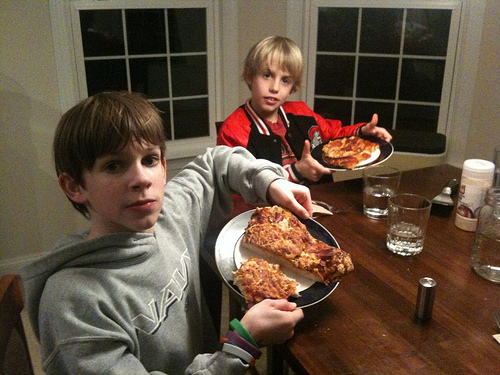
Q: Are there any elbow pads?
A: No, there are no elbow pads.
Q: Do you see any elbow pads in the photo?
A: No, there are no elbow pads.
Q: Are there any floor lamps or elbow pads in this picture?
A: No, there are no elbow pads or floor lamps.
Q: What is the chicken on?
A: The chicken is on the plate.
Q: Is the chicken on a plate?
A: Yes, the chicken is on a plate.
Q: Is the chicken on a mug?
A: No, the chicken is on a plate.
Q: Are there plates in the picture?
A: Yes, there is a plate.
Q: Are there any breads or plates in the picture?
A: Yes, there is a plate.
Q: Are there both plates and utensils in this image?
A: No, there is a plate but no utensils.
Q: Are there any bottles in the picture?
A: No, there are no bottles.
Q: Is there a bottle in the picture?
A: No, there are no bottles.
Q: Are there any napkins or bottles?
A: No, there are no bottles or napkins.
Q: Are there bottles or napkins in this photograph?
A: No, there are no bottles or napkins.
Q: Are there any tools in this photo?
A: No, there are no tools.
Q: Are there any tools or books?
A: No, there are no tools or books.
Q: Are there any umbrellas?
A: No, there are no umbrellas.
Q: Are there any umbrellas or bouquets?
A: No, there are no umbrellas or bouquets.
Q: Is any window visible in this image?
A: Yes, there is a window.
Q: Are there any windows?
A: Yes, there is a window.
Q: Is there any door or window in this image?
A: Yes, there is a window.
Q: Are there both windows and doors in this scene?
A: No, there is a window but no doors.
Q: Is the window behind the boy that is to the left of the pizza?
A: Yes, the window is behind the boy.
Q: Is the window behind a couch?
A: No, the window is behind the boy.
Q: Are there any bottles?
A: No, there are no bottles.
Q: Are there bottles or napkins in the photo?
A: No, there are no bottles or napkins.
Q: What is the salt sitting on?
A: The salt is sitting on the table.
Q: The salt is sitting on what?
A: The salt is sitting on the table.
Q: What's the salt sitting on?
A: The salt is sitting on the table.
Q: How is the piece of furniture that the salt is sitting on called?
A: The piece of furniture is a table.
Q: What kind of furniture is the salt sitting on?
A: The salt is sitting on the table.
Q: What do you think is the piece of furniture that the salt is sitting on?
A: The piece of furniture is a table.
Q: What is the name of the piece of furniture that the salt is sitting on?
A: The piece of furniture is a table.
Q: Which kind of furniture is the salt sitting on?
A: The salt is sitting on the table.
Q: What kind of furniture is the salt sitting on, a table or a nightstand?
A: The salt is sitting on a table.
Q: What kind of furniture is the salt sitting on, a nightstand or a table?
A: The salt is sitting on a table.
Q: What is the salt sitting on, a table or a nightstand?
A: The salt is sitting on a table.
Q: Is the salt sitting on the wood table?
A: Yes, the salt is sitting on the table.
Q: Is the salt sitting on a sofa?
A: No, the salt is sitting on the table.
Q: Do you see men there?
A: No, there are no men.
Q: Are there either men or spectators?
A: No, there are no men or spectators.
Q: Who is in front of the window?
A: The boy is in front of the window.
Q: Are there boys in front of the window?
A: Yes, there is a boy in front of the window.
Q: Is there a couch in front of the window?
A: No, there is a boy in front of the window.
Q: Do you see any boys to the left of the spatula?
A: Yes, there is a boy to the left of the spatula.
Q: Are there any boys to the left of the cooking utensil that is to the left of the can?
A: Yes, there is a boy to the left of the spatula.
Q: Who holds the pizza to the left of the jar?
A: The boy holds the pizza.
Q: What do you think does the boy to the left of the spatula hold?
A: The boy holds the pizza.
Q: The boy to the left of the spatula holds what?
A: The boy holds the pizza.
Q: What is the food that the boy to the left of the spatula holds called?
A: The food is a pizza.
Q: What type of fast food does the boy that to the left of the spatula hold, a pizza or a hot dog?
A: The boy holds a pizza.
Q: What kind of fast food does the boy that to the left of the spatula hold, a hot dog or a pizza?
A: The boy holds a pizza.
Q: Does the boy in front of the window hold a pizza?
A: Yes, the boy holds a pizza.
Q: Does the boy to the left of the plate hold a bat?
A: No, the boy holds a pizza.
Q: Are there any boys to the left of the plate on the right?
A: Yes, there is a boy to the left of the plate.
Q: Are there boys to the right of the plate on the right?
A: No, the boy is to the left of the plate.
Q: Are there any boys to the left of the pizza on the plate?
A: Yes, there is a boy to the left of the pizza.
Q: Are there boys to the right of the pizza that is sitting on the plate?
A: No, the boy is to the left of the pizza.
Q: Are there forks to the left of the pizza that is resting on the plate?
A: No, there is a boy to the left of the pizza.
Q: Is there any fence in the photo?
A: No, there are no fences.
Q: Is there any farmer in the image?
A: No, there are no farmers.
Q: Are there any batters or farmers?
A: No, there are no farmers or batters.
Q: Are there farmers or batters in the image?
A: No, there are no farmers or batters.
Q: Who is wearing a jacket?
A: The boy is wearing a jacket.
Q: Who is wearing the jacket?
A: The boy is wearing a jacket.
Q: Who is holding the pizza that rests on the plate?
A: The boy is holding the pizza.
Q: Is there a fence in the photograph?
A: No, there are no fences.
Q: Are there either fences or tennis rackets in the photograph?
A: No, there are no fences or tennis rackets.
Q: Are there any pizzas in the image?
A: Yes, there is a pizza.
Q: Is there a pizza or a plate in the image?
A: Yes, there is a pizza.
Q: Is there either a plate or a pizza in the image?
A: Yes, there is a pizza.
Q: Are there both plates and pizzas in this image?
A: Yes, there are both a pizza and a plate.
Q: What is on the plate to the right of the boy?
A: The pizza is on the plate.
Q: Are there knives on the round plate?
A: No, there is a pizza on the plate.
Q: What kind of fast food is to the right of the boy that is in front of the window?
A: The food is a pizza.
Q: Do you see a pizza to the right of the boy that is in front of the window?
A: Yes, there is a pizza to the right of the boy.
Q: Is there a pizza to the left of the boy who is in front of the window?
A: No, the pizza is to the right of the boy.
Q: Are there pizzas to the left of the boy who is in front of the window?
A: No, the pizza is to the right of the boy.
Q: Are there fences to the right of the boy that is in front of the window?
A: No, there is a pizza to the right of the boy.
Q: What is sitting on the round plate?
A: The pizza is sitting on the plate.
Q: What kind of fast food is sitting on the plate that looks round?
A: The food is a pizza.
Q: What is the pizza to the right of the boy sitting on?
A: The pizza is sitting on the plate.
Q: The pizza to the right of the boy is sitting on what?
A: The pizza is sitting on the plate.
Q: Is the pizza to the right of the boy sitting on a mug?
A: No, the pizza is sitting on the plate.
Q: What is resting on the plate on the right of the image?
A: The pizza is resting on the plate.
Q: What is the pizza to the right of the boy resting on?
A: The pizza is resting on the plate.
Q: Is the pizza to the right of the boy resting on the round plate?
A: Yes, the pizza is resting on the plate.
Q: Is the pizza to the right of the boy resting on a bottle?
A: No, the pizza is resting on the plate.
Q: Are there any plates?
A: Yes, there is a plate.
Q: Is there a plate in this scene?
A: Yes, there is a plate.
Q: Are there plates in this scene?
A: Yes, there is a plate.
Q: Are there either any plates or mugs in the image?
A: Yes, there is a plate.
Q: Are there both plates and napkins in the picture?
A: No, there is a plate but no napkins.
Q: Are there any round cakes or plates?
A: Yes, there is a round plate.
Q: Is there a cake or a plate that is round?
A: Yes, the plate is round.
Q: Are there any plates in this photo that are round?
A: Yes, there is a round plate.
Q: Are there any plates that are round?
A: Yes, there is a plate that is round.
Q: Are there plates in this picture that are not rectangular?
A: Yes, there is a round plate.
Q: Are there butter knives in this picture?
A: No, there are no butter knives.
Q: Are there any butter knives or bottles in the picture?
A: No, there are no butter knives or bottles.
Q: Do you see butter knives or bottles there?
A: No, there are no butter knives or bottles.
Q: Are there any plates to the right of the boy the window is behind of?
A: Yes, there is a plate to the right of the boy.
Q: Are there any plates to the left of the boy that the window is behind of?
A: No, the plate is to the right of the boy.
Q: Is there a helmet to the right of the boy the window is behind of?
A: No, there is a plate to the right of the boy.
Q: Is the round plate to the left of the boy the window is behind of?
A: No, the plate is to the right of the boy.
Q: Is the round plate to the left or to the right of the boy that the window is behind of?
A: The plate is to the right of the boy.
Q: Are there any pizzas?
A: Yes, there is a pizza.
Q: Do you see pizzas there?
A: Yes, there is a pizza.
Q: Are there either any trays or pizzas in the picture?
A: Yes, there is a pizza.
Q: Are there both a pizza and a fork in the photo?
A: No, there is a pizza but no forks.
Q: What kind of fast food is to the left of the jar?
A: The food is a pizza.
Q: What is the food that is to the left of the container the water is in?
A: The food is a pizza.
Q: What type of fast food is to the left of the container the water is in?
A: The food is a pizza.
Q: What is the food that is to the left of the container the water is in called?
A: The food is a pizza.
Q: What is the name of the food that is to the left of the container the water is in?
A: The food is a pizza.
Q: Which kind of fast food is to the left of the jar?
A: The food is a pizza.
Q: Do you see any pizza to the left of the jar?
A: Yes, there is a pizza to the left of the jar.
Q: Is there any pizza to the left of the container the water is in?
A: Yes, there is a pizza to the left of the jar.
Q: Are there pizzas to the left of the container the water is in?
A: Yes, there is a pizza to the left of the jar.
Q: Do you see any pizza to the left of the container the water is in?
A: Yes, there is a pizza to the left of the jar.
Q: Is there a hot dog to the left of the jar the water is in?
A: No, there is a pizza to the left of the jar.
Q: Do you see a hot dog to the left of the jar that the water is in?
A: No, there is a pizza to the left of the jar.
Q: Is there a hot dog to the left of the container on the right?
A: No, there is a pizza to the left of the jar.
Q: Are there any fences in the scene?
A: No, there are no fences.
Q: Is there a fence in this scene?
A: No, there are no fences.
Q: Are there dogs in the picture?
A: No, there are no dogs.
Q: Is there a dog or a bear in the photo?
A: No, there are no dogs or bears.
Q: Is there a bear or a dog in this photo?
A: No, there are no dogs or bears.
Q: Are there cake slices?
A: No, there are no cake slices.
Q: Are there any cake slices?
A: No, there are no cake slices.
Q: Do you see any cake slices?
A: No, there are no cake slices.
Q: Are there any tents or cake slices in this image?
A: No, there are no cake slices or tents.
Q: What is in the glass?
A: The liquid is in the glass.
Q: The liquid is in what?
A: The liquid is in the glass.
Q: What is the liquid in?
A: The liquid is in the glass.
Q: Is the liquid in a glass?
A: Yes, the liquid is in a glass.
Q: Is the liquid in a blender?
A: No, the liquid is in a glass.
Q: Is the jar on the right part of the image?
A: Yes, the jar is on the right of the image.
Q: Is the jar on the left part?
A: No, the jar is on the right of the image.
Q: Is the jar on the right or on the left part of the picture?
A: The jar is on the right of the image.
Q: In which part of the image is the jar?
A: The jar is on the right of the image.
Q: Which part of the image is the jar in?
A: The jar is on the right of the image.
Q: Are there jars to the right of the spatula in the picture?
A: Yes, there is a jar to the right of the spatula.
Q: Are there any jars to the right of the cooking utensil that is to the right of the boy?
A: Yes, there is a jar to the right of the spatula.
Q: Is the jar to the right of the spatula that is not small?
A: Yes, the jar is to the right of the spatula.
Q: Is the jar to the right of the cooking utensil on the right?
A: Yes, the jar is to the right of the spatula.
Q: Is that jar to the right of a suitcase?
A: No, the jar is to the right of the spatula.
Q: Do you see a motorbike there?
A: No, there are no motorcycles.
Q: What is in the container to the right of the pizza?
A: The water is in the jar.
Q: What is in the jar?
A: The water is in the jar.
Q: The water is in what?
A: The water is in the jar.